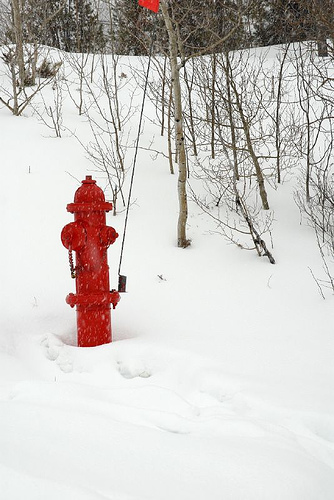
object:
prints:
[116, 355, 156, 383]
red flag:
[115, 0, 159, 294]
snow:
[0, 36, 333, 496]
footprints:
[40, 338, 76, 374]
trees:
[284, 0, 334, 215]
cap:
[105, 228, 119, 242]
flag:
[136, 1, 158, 11]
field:
[6, 49, 324, 493]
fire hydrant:
[59, 173, 122, 348]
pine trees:
[106, 0, 154, 59]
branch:
[245, 83, 267, 127]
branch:
[236, 71, 248, 106]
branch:
[179, 112, 241, 135]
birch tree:
[136, 3, 221, 246]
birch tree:
[1, 56, 34, 117]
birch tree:
[7, 0, 39, 85]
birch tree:
[65, 44, 90, 112]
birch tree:
[206, 50, 277, 204]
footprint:
[37, 334, 60, 360]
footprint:
[55, 351, 74, 373]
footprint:
[113, 352, 136, 379]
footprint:
[135, 355, 152, 377]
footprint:
[152, 414, 193, 435]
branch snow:
[192, 152, 276, 266]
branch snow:
[81, 125, 131, 174]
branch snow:
[31, 88, 63, 141]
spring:
[116, 272, 128, 293]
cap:
[62, 169, 120, 215]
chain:
[66, 244, 79, 281]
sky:
[219, 1, 303, 43]